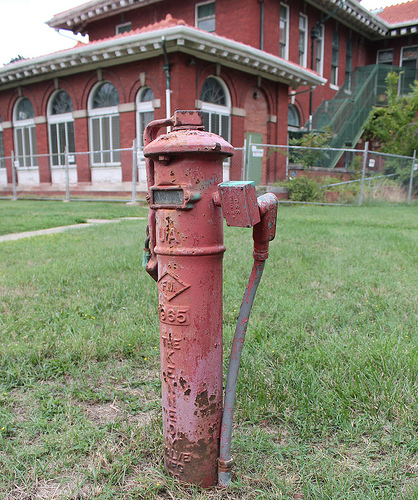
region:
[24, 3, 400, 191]
large red brick building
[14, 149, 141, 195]
silver chain link fence surrounding building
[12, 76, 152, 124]
row of arched windows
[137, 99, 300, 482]
rusty metal fire hydrant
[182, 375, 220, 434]
area of chipping paint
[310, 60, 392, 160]
stairway going up building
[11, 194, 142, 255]
concrete pathway to building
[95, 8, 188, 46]
red shingles on roof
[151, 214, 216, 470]
lettering on metal pipe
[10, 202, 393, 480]
large green field in front of house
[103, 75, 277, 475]
Red hydrant sticking out of ground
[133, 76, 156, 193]
Large window on a building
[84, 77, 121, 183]
Large window on a building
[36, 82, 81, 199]
Large window on a building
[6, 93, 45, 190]
Large window on a building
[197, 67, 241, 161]
Large window on a building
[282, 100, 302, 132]
Large window on a building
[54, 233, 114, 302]
Part of the green grass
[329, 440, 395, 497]
Part of the green grass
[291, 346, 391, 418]
Part of the green grass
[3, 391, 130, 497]
The grass has bare patches.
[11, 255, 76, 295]
The grass in the background is green.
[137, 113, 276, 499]
The fire hydrant is red.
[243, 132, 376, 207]
The gate in the background is metal.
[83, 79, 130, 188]
The window is large.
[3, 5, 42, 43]
The sky is clear.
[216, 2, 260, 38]
The building is red.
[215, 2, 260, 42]
The building is made of brick.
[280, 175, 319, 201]
The bush is green.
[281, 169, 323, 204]
The bush is small.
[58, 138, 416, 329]
the fire hydrant is red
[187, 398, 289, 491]
a metal pole is next to the hydrant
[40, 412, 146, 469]
the grass is dead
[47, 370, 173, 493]
a patch of dirt and grass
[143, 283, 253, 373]
numbers are on the hydrant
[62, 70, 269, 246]
a building is behind the hydrant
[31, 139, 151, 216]
the building has windows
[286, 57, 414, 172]
a stairway leads upstairs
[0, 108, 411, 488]
tall red fire hydrant on grassy lot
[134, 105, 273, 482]
handle and pipe on different sides of rusted hydrant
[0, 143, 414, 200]
metal fencing with silver poles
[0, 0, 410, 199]
brick building with decorative white edging on roof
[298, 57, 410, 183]
enclosed outer green staircase by exterior wall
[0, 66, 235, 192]
arched windows over long narrow windows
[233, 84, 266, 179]
solid arch above green door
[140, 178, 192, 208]
grey metal panel on front of hydrant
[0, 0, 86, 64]
bright light over corner of roofs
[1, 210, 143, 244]
narrow cement walkway through grass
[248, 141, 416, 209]
a gray chain link fence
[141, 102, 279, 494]
an old red fire hydrant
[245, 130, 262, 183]
a green door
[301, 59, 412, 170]
a covered stairway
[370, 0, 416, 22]
a roof of a building